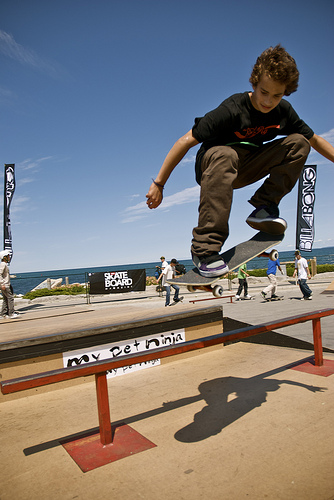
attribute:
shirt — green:
[238, 265, 245, 278]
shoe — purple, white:
[191, 250, 228, 276]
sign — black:
[89, 269, 147, 294]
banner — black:
[87, 267, 145, 295]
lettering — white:
[104, 271, 132, 290]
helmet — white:
[0, 247, 14, 262]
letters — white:
[82, 250, 171, 295]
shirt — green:
[239, 265, 248, 282]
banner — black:
[78, 256, 153, 301]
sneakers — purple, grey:
[176, 199, 297, 274]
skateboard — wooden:
[161, 227, 285, 304]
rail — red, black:
[170, 308, 317, 346]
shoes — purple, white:
[190, 208, 286, 277]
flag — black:
[297, 161, 313, 251]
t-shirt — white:
[292, 258, 307, 281]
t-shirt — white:
[158, 266, 173, 287]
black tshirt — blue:
[190, 90, 315, 184]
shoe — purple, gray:
[189, 247, 230, 277]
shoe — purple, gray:
[244, 206, 288, 233]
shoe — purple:
[189, 256, 230, 279]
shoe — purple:
[244, 207, 285, 231]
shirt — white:
[159, 262, 174, 287]